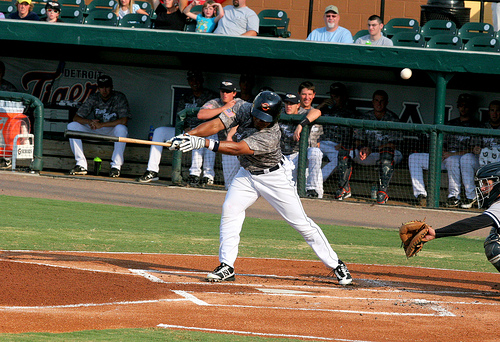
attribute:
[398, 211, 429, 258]
glove — brown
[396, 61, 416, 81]
baseball — flying, white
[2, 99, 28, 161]
dispenser — orange, red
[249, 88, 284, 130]
helmet — black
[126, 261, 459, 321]
base — white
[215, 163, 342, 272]
pants — white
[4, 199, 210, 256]
grass — green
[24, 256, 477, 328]
lines — white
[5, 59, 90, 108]
logo — Detroit Tiger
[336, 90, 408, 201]
man — white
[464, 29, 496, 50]
seat — green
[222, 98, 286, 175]
shirt — gray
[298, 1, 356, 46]
man — white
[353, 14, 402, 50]
man — white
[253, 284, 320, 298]
home plate — triangular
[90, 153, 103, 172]
object — green